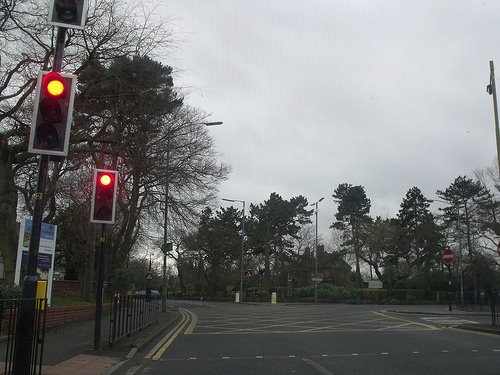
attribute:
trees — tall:
[241, 189, 311, 296]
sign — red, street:
[429, 233, 465, 278]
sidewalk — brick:
[0, 292, 177, 373]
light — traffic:
[92, 168, 115, 219]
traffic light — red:
[92, 164, 119, 224]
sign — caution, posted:
[440, 245, 455, 265]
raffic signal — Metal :
[5, 44, 167, 269]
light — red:
[89, 169, 120, 224]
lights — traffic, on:
[34, 71, 120, 226]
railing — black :
[108, 295, 158, 345]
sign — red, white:
[34, 54, 102, 197]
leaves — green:
[200, 214, 357, 299]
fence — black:
[107, 289, 162, 347]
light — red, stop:
[38, 65, 70, 150]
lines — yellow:
[151, 309, 208, 359]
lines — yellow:
[199, 315, 416, 331]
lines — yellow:
[299, 355, 336, 373]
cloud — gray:
[321, 36, 411, 103]